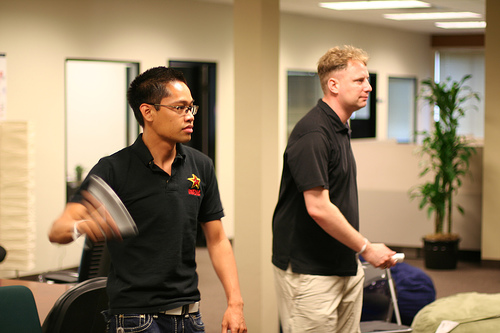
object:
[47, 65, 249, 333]
man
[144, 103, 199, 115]
glasses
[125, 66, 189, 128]
hair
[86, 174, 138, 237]
wii remote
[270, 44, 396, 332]
man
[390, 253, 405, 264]
wii remote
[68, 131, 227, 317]
shirt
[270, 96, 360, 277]
shirt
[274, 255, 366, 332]
pants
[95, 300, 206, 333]
jeans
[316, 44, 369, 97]
hair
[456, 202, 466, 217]
leaves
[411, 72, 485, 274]
plant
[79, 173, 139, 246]
game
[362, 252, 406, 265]
game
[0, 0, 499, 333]
photo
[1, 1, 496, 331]
room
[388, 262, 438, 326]
luggage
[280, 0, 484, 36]
ceiling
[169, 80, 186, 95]
light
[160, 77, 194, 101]
forehead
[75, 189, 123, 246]
hand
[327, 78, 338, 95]
ear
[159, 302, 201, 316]
belt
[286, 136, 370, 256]
arm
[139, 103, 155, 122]
ear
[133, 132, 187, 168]
collar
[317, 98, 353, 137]
collar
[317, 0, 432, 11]
light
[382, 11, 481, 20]
light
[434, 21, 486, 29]
light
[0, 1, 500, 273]
walls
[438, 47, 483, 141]
mini blinds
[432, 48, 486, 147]
window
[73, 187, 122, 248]
motion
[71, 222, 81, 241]
bangle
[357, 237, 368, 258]
bangle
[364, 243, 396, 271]
hand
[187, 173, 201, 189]
star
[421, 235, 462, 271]
vase